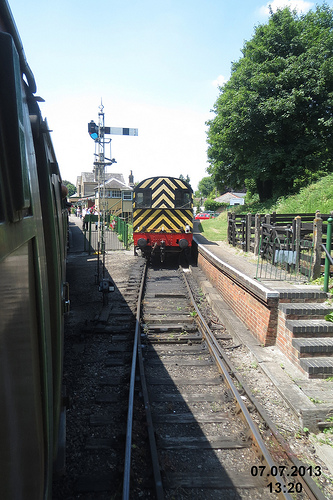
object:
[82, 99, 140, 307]
control tower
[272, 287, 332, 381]
ladders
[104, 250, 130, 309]
rocks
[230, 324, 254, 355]
rocks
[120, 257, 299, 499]
track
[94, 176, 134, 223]
building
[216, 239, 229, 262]
ground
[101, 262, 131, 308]
ground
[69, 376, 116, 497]
ground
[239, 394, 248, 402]
stone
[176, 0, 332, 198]
bush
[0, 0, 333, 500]
train stop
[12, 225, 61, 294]
wall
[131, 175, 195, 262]
train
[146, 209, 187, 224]
stripes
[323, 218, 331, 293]
post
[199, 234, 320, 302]
platform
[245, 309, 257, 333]
brick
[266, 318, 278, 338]
brick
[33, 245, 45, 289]
paint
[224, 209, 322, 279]
fence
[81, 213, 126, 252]
fence